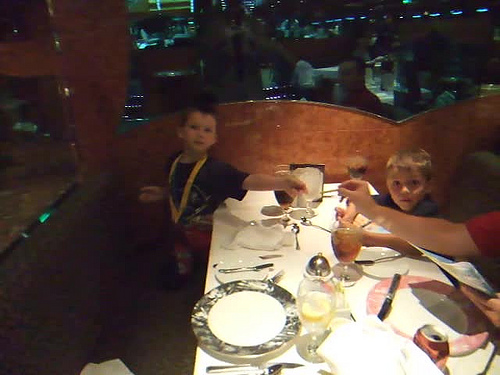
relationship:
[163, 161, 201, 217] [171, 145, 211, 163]
lanyard on neck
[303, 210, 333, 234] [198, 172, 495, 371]
spoon on table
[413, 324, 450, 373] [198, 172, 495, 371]
can on table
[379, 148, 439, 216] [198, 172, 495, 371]
boy sitting at table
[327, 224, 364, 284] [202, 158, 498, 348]
glass on table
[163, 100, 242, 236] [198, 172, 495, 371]
boy sitting at table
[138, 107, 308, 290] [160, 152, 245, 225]
boy wearing shirt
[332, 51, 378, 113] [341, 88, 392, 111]
man wearing shirt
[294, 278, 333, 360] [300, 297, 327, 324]
glass filled with wine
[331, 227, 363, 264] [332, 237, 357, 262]
glass with tea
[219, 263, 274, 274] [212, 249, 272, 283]
knife on plate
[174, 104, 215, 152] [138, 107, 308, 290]
head of boy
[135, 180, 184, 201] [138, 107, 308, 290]
arm of boy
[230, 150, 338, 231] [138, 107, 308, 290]
arm on boy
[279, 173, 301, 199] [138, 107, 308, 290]
hand on boy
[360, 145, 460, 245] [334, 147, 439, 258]
head on boy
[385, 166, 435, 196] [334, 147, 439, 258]
eye on boy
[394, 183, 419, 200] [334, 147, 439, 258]
nose on boy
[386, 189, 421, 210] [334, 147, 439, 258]
mouth on boy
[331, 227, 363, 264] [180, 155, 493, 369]
glass on table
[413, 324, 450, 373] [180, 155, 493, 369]
can on table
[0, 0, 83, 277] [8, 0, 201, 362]
mirror on wall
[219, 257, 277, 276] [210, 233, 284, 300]
knife on plate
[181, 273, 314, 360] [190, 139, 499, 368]
plate on table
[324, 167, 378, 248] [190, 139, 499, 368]
hands on table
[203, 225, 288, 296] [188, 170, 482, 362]
plate on table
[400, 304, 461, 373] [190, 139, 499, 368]
can on table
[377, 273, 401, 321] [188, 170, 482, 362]
knife on table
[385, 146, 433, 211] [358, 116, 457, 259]
head on boy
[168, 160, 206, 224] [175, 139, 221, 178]
lanyard on neck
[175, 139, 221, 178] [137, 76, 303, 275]
neck on boy